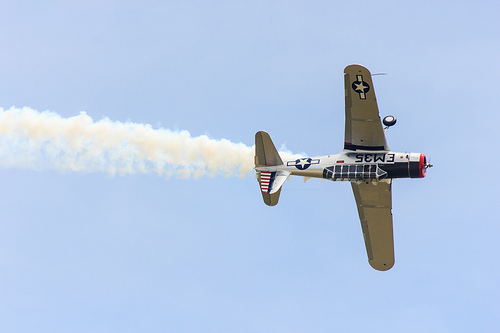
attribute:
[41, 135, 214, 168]
exhaust — white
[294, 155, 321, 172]
star — white, blue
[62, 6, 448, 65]
sky — blue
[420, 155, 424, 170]
paint — red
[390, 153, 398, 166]
letter — blue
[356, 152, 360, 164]
number — blue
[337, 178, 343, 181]
metal — silver